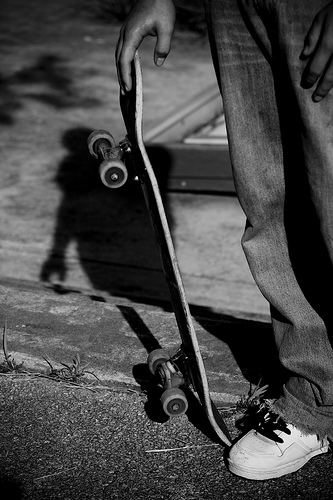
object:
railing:
[142, 79, 236, 192]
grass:
[0, 317, 269, 407]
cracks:
[0, 361, 148, 396]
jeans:
[204, 0, 333, 442]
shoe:
[227, 411, 329, 481]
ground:
[0, 0, 333, 499]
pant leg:
[205, 1, 332, 442]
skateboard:
[88, 49, 233, 446]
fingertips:
[125, 85, 131, 91]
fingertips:
[121, 91, 125, 96]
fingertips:
[155, 62, 164, 67]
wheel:
[161, 387, 188, 417]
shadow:
[40, 126, 284, 399]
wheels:
[87, 129, 128, 189]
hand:
[115, 0, 176, 96]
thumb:
[154, 25, 174, 67]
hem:
[272, 384, 331, 441]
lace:
[253, 411, 291, 444]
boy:
[115, 0, 333, 482]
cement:
[0, 369, 333, 499]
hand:
[302, 3, 332, 102]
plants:
[0, 316, 102, 385]